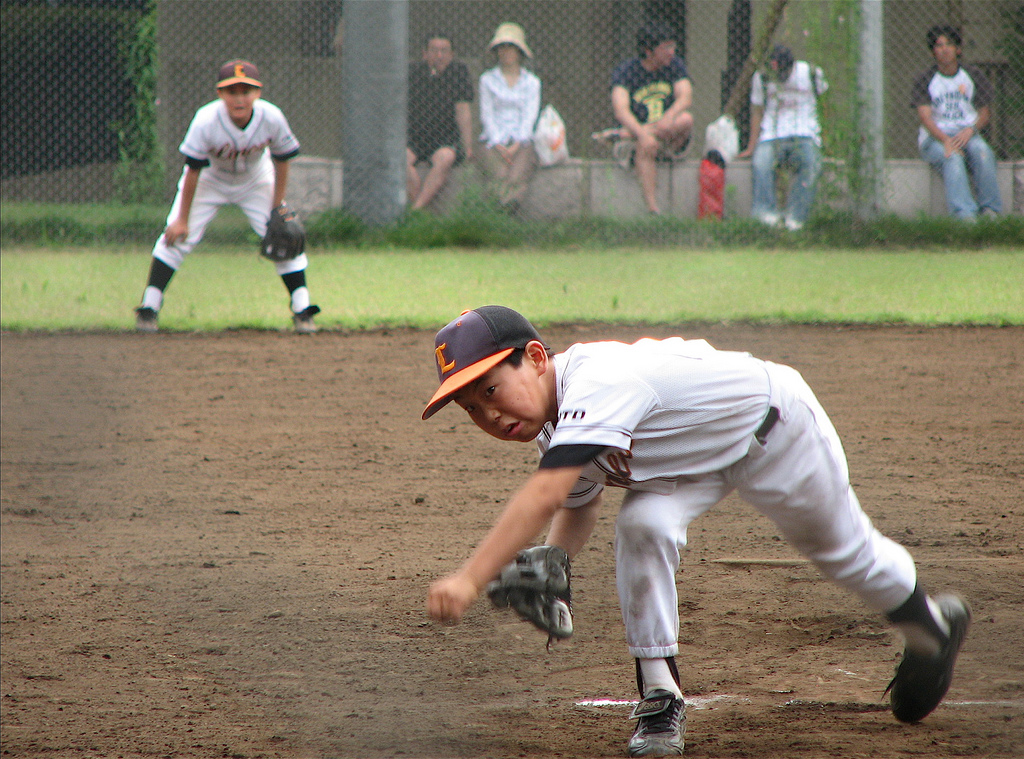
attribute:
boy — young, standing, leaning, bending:
[420, 303, 974, 757]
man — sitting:
[914, 24, 1007, 226]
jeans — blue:
[919, 134, 1006, 215]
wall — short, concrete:
[277, 150, 1020, 226]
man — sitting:
[747, 50, 836, 234]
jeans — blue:
[749, 142, 829, 225]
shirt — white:
[474, 64, 542, 143]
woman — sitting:
[474, 17, 544, 224]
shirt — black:
[407, 63, 471, 150]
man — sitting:
[405, 33, 477, 221]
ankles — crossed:
[403, 190, 429, 216]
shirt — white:
[750, 61, 829, 146]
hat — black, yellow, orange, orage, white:
[416, 299, 542, 420]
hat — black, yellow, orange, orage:
[213, 55, 267, 94]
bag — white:
[533, 105, 571, 169]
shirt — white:
[919, 71, 990, 143]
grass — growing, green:
[2, 238, 1023, 331]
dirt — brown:
[2, 327, 1021, 755]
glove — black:
[494, 542, 577, 642]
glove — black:
[260, 206, 306, 266]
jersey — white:
[541, 331, 769, 492]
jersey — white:
[181, 100, 298, 180]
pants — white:
[146, 158, 284, 279]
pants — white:
[611, 356, 923, 662]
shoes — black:
[623, 583, 974, 756]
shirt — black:
[608, 61, 684, 131]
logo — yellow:
[629, 84, 670, 121]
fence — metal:
[3, 5, 1023, 243]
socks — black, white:
[141, 250, 316, 317]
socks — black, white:
[628, 579, 931, 697]